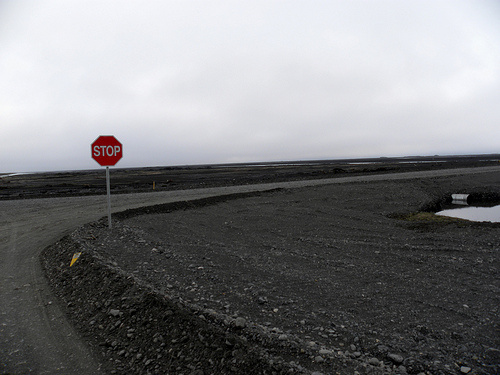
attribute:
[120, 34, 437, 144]
sky — very grey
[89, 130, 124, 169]
sign — red, white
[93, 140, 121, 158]
word — white, stop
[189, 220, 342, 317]
some dirt — dark brown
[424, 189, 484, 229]
pond — small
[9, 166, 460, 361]
road — grey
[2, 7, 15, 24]
sky — small bit, blue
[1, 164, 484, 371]
road — empty, unpaved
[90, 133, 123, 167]
sign — red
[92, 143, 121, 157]
lettering — white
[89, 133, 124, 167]
edge — white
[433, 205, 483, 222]
water — still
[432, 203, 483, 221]
water — standing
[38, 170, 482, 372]
ground — rocky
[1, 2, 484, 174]
sky — cloudy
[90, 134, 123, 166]
stop sign — red